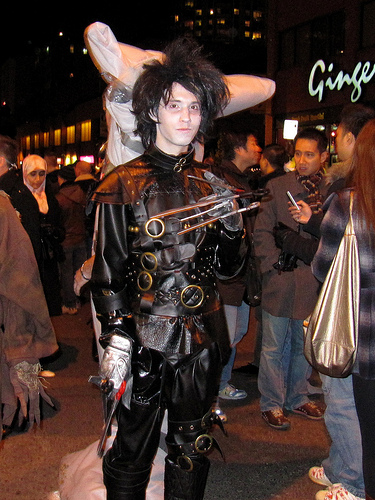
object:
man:
[252, 127, 325, 432]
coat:
[252, 170, 329, 320]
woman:
[9, 154, 68, 378]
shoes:
[308, 464, 366, 500]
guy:
[86, 39, 251, 500]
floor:
[0, 288, 375, 499]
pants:
[100, 347, 224, 500]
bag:
[301, 187, 360, 378]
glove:
[98, 335, 134, 411]